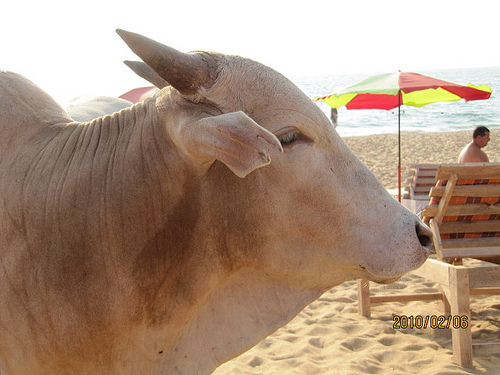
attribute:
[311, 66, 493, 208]
umbrella — yellow, red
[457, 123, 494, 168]
man — shirtless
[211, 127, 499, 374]
beach — soft, sandy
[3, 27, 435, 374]
cow — brown, brahma, large, light brown, big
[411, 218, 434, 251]
nostril — black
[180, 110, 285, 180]
ear — partially clipped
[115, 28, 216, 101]
horn — sharp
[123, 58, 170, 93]
horn — pointy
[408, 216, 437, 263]
nose — pink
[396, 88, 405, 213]
pole — tall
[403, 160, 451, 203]
beach chair — wooden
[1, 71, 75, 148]
hump — fatty deposit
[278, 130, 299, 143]
eyelashes — white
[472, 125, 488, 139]
hair — dark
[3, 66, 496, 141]
water — in distance